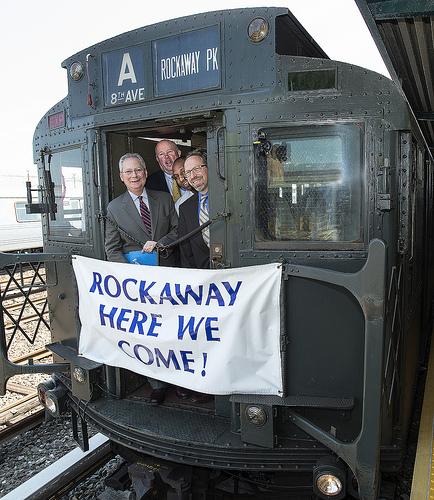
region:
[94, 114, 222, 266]
people standing in doorway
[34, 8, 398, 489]
back of passenger train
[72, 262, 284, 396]
blue words on white banner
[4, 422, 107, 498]
train track in gravel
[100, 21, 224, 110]
white words on sign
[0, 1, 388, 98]
sunlight in daytime sky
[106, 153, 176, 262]
man in suit an tie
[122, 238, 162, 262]
hand over blue folder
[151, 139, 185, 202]
man in yellow tie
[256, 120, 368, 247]
train window with reflection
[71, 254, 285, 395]
a sign proclaiming the destination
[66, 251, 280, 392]
a banner proclaiming the destination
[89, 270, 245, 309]
a resort in Queens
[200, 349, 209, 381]
an indication of intensity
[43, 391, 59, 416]
headlight on the car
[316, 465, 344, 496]
headlight on the car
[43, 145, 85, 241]
window in the train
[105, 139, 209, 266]
people posing for a photo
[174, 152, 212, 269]
man with a beard wearing glasses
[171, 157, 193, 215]
man in light blue shirt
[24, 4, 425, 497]
the train is at a terminal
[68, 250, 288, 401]
a sign is on the train car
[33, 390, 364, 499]
the lights are on the bumper of the train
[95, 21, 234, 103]
the train marque has the destination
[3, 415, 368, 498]
the train is on the tracks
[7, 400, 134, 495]
gravel surrounds the train tracks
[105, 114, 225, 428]
the back door of the train is open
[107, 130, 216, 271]
four men are standing in the doorway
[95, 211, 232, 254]
a safety strap is across the doorway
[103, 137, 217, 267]
the men are wearing suits and ties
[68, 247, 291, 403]
hung sign on train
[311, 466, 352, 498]
light on train car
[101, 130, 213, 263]
people riding on train car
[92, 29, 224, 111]
sign noting train route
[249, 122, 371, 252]
window to train car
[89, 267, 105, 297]
blue lettering on sign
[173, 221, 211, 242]
rope on train car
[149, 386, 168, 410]
shoe on man on train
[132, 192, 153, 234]
tie on man on train car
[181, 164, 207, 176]
glasses worn by man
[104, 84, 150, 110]
the words "8th ave."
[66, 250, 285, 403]
a white sign with blue letters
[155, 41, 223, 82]
the words "rockway pk"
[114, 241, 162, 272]
blue file folders in someone's hand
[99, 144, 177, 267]
a man with a red tie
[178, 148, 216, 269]
a man in a black jacket and blue shirt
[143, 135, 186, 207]
a man with a yellow tie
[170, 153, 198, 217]
a man in a light grey jacket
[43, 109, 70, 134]
a red exp sign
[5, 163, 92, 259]
a silver train sitting on the tracks